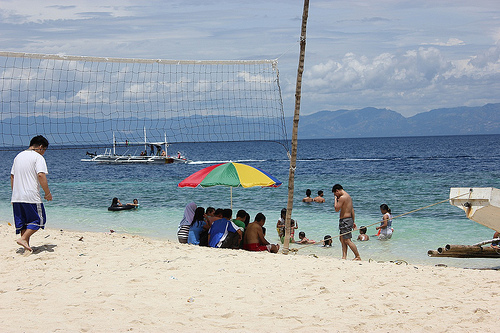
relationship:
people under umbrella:
[175, 202, 275, 251] [180, 158, 283, 195]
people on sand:
[175, 202, 275, 251] [3, 225, 499, 332]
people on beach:
[175, 202, 275, 251] [1, 185, 496, 329]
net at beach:
[1, 49, 291, 165] [1, 185, 496, 329]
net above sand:
[1, 49, 291, 165] [3, 225, 499, 332]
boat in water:
[86, 126, 183, 169] [72, 152, 226, 190]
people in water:
[274, 195, 396, 257] [254, 198, 445, 263]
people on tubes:
[110, 197, 142, 207] [106, 205, 141, 213]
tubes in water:
[106, 205, 141, 213] [72, 152, 226, 190]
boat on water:
[86, 126, 183, 169] [72, 152, 226, 190]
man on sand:
[7, 132, 61, 257] [3, 225, 499, 332]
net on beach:
[1, 49, 291, 165] [1, 185, 496, 329]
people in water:
[274, 195, 396, 257] [72, 152, 226, 190]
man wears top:
[7, 132, 61, 257] [8, 148, 47, 208]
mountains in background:
[1, 100, 498, 145] [3, 130, 498, 133]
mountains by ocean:
[1, 100, 498, 145] [1, 133, 499, 269]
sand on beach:
[3, 225, 499, 332] [1, 185, 496, 329]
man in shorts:
[7, 132, 61, 257] [10, 197, 48, 231]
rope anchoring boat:
[289, 193, 466, 254] [441, 174, 498, 235]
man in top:
[7, 132, 61, 257] [8, 148, 47, 208]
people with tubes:
[175, 202, 275, 251] [106, 205, 141, 213]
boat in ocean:
[86, 126, 183, 169] [1, 133, 499, 269]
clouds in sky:
[10, 51, 495, 100] [2, 4, 496, 103]